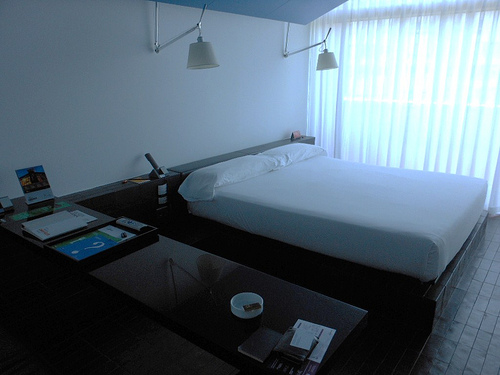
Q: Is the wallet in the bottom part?
A: Yes, the wallet is in the bottom of the image.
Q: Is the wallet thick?
A: Yes, the wallet is thick.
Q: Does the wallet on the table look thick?
A: Yes, the wallet is thick.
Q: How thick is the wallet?
A: The wallet is thick.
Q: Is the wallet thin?
A: No, the wallet is thick.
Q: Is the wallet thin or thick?
A: The wallet is thick.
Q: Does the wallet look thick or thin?
A: The wallet is thick.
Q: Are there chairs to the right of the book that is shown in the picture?
A: No, there is a wallet to the right of the book.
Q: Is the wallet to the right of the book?
A: Yes, the wallet is to the right of the book.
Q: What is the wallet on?
A: The wallet is on the table.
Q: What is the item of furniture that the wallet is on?
A: The piece of furniture is a table.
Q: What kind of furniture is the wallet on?
A: The wallet is on the table.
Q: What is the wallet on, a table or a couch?
A: The wallet is on a table.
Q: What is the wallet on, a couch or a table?
A: The wallet is on a table.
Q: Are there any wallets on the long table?
A: Yes, there is a wallet on the table.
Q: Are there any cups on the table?
A: No, there is a wallet on the table.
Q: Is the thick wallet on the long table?
A: Yes, the wallet is on the table.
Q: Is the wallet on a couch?
A: No, the wallet is on the table.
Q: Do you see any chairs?
A: No, there are no chairs.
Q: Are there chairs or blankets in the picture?
A: No, there are no chairs or blankets.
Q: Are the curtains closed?
A: Yes, the curtains are closed.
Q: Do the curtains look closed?
A: Yes, the curtains are closed.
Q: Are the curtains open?
A: No, the curtains are closed.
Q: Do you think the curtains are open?
A: No, the curtains are closed.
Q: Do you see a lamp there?
A: Yes, there is a lamp.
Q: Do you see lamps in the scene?
A: Yes, there is a lamp.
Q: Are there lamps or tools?
A: Yes, there is a lamp.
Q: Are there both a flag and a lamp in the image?
A: No, there is a lamp but no flags.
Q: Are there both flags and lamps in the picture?
A: No, there is a lamp but no flags.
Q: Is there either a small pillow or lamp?
A: Yes, there is a small lamp.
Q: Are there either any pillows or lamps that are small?
A: Yes, the lamp is small.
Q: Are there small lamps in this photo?
A: Yes, there is a small lamp.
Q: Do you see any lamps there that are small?
A: Yes, there is a lamp that is small.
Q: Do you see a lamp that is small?
A: Yes, there is a lamp that is small.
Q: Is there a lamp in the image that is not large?
A: Yes, there is a small lamp.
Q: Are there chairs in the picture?
A: No, there are no chairs.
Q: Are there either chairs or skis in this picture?
A: No, there are no chairs or skis.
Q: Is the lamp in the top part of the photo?
A: Yes, the lamp is in the top of the image.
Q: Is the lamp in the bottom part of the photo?
A: No, the lamp is in the top of the image.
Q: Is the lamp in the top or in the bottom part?
A: The lamp is in the top of the image.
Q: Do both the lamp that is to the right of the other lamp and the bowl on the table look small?
A: Yes, both the lamp and the bowl are small.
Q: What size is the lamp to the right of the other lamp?
A: The lamp is small.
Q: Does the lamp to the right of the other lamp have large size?
A: No, the lamp is small.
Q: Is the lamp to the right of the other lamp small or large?
A: The lamp is small.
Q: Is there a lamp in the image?
A: Yes, there is a lamp.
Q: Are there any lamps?
A: Yes, there is a lamp.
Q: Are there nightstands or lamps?
A: Yes, there is a lamp.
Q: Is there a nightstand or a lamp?
A: Yes, there is a lamp.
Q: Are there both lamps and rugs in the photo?
A: No, there is a lamp but no rugs.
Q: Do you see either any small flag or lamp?
A: Yes, there is a small lamp.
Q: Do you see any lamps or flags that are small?
A: Yes, the lamp is small.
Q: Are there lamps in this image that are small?
A: Yes, there is a small lamp.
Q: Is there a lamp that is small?
A: Yes, there is a lamp that is small.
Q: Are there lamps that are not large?
A: Yes, there is a small lamp.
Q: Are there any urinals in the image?
A: No, there are no urinals.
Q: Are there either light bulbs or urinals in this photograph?
A: No, there are no urinals or light bulbs.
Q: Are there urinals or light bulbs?
A: No, there are no urinals or light bulbs.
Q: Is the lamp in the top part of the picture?
A: Yes, the lamp is in the top of the image.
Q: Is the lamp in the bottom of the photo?
A: No, the lamp is in the top of the image.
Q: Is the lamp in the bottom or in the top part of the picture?
A: The lamp is in the top of the image.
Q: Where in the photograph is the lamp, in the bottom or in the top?
A: The lamp is in the top of the image.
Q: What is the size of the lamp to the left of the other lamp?
A: The lamp is small.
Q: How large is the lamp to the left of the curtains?
A: The lamp is small.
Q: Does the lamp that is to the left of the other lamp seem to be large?
A: No, the lamp is small.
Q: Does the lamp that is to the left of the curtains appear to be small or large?
A: The lamp is small.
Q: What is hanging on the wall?
A: The lamp is hanging on the wall.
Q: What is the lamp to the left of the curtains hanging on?
A: The lamp is hanging on the wall.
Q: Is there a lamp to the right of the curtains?
A: No, the lamp is to the left of the curtains.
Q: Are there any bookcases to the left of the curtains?
A: No, there is a lamp to the left of the curtains.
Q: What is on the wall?
A: The lamp is on the wall.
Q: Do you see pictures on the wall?
A: No, there is a lamp on the wall.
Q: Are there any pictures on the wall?
A: No, there is a lamp on the wall.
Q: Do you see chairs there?
A: No, there are no chairs.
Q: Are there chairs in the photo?
A: No, there are no chairs.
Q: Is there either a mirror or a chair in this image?
A: No, there are no chairs or mirrors.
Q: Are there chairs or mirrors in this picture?
A: No, there are no chairs or mirrors.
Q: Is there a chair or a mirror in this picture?
A: No, there are no chairs or mirrors.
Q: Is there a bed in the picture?
A: Yes, there is a bed.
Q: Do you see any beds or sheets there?
A: Yes, there is a bed.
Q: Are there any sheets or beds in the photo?
A: Yes, there is a bed.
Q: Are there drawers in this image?
A: No, there are no drawers.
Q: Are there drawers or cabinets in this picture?
A: No, there are no drawers or cabinets.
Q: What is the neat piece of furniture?
A: The piece of furniture is a bed.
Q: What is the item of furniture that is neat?
A: The piece of furniture is a bed.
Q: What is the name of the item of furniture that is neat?
A: The piece of furniture is a bed.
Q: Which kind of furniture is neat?
A: The furniture is a bed.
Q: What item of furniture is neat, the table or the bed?
A: The bed is neat.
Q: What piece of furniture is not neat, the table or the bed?
A: The table is not neat.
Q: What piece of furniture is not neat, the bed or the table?
A: The table is not neat.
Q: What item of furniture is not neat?
A: The piece of furniture is a table.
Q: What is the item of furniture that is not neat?
A: The piece of furniture is a table.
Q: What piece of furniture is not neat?
A: The piece of furniture is a table.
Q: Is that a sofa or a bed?
A: That is a bed.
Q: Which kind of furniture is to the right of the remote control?
A: The piece of furniture is a bed.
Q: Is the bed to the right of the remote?
A: Yes, the bed is to the right of the remote.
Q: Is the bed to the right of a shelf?
A: No, the bed is to the right of the remote.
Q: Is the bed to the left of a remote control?
A: No, the bed is to the right of a remote control.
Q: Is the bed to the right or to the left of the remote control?
A: The bed is to the right of the remote control.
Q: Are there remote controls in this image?
A: Yes, there is a remote control.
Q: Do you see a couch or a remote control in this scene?
A: Yes, there is a remote control.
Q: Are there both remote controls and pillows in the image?
A: Yes, there are both a remote control and a pillow.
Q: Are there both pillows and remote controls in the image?
A: Yes, there are both a remote control and a pillow.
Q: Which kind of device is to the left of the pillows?
A: The device is a remote control.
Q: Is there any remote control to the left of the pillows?
A: Yes, there is a remote control to the left of the pillows.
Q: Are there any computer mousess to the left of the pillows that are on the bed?
A: No, there is a remote control to the left of the pillows.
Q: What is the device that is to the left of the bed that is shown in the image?
A: The device is a remote control.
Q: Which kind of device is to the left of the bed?
A: The device is a remote control.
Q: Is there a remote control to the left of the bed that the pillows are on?
A: Yes, there is a remote control to the left of the bed.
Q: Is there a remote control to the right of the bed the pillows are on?
A: No, the remote control is to the left of the bed.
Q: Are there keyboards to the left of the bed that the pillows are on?
A: No, there is a remote control to the left of the bed.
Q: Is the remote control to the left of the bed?
A: Yes, the remote control is to the left of the bed.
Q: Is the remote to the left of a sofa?
A: No, the remote is to the left of the bed.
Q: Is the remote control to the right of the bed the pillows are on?
A: No, the remote control is to the left of the bed.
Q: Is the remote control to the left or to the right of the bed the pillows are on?
A: The remote control is to the left of the bed.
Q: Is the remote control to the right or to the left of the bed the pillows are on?
A: The remote control is to the left of the bed.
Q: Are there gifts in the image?
A: No, there are no gifts.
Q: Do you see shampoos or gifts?
A: No, there are no gifts or shampoos.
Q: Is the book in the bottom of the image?
A: Yes, the book is in the bottom of the image.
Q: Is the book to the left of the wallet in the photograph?
A: Yes, the book is to the left of the wallet.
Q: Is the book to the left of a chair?
A: No, the book is to the left of the wallet.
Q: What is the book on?
A: The book is on the table.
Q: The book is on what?
A: The book is on the table.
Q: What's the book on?
A: The book is on the table.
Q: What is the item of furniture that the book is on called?
A: The piece of furniture is a table.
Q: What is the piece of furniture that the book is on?
A: The piece of furniture is a table.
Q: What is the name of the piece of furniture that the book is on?
A: The piece of furniture is a table.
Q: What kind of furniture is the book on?
A: The book is on the table.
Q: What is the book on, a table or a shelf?
A: The book is on a table.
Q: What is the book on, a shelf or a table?
A: The book is on a table.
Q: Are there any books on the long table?
A: Yes, there is a book on the table.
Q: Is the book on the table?
A: Yes, the book is on the table.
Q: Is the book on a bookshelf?
A: No, the book is on the table.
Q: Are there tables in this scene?
A: Yes, there is a table.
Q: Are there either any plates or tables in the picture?
A: Yes, there is a table.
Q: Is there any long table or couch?
A: Yes, there is a long table.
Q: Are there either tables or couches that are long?
A: Yes, the table is long.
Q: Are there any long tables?
A: Yes, there is a long table.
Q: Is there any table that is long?
A: Yes, there is a table that is long.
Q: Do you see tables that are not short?
A: Yes, there is a long table.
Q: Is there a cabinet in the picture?
A: No, there are no cabinets.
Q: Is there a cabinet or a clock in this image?
A: No, there are no cabinets or clocks.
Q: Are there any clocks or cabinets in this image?
A: No, there are no cabinets or clocks.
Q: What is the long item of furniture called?
A: The piece of furniture is a table.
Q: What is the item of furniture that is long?
A: The piece of furniture is a table.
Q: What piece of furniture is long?
A: The piece of furniture is a table.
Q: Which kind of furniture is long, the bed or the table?
A: The table is long.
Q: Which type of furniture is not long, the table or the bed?
A: The bed is not long.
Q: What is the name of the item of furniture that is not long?
A: The piece of furniture is a bed.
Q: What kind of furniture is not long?
A: The furniture is a bed.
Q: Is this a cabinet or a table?
A: This is a table.